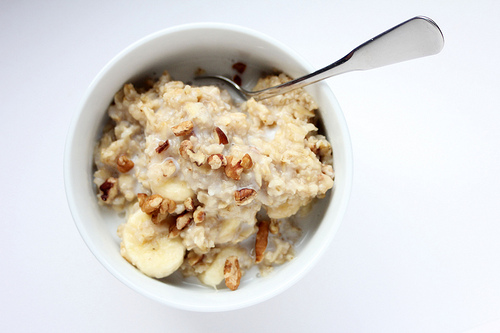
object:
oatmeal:
[98, 64, 328, 294]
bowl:
[64, 18, 353, 317]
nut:
[219, 151, 254, 183]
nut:
[233, 186, 252, 201]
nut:
[191, 190, 209, 206]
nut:
[157, 137, 169, 159]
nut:
[116, 152, 133, 171]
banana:
[116, 210, 188, 281]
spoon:
[187, 15, 449, 105]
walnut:
[153, 193, 175, 224]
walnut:
[139, 189, 162, 218]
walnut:
[173, 208, 194, 233]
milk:
[105, 61, 312, 282]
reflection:
[255, 79, 304, 102]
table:
[0, 2, 498, 333]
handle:
[255, 20, 448, 102]